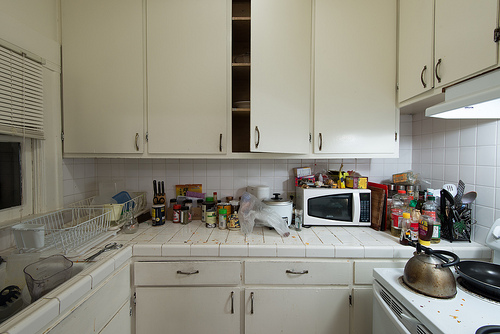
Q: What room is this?
A: Kitchen.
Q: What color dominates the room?
A: White.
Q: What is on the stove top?
A: Tea kettle.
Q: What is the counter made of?
A: Tile.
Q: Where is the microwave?
A: On the tile counter.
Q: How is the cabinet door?
A: Partially open.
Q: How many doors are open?
A: 1.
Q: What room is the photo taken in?
A: Kitchen.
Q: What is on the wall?
A: Tile.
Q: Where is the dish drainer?
A: Counter top.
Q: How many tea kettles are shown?
A: 1.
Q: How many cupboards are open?
A: One.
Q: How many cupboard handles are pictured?
A: 8.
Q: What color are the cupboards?
A: White.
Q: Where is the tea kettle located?
A: On the stove.